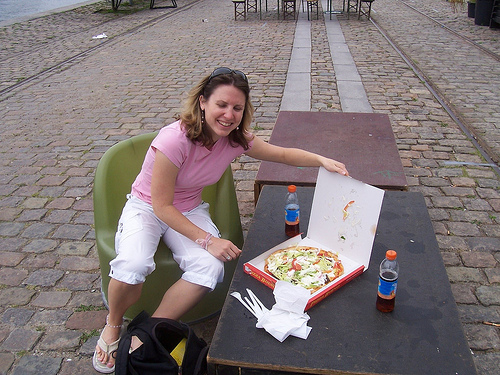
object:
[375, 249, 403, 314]
bottle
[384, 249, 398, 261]
cap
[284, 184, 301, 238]
bottle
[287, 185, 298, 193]
cap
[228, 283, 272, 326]
cutlery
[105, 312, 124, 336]
ankle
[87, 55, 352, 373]
woman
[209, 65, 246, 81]
sunglasses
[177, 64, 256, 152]
hair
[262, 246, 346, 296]
pizza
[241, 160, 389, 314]
box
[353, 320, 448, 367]
table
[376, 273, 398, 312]
drink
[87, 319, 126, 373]
flip flop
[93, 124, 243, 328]
chair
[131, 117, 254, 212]
shirt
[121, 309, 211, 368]
bag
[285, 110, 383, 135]
table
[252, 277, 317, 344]
napkins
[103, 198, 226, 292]
pants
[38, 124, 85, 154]
cobblestones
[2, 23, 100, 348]
road